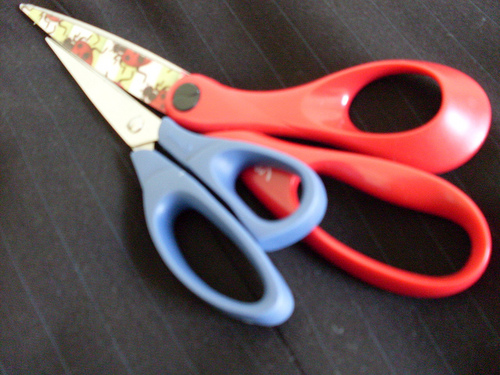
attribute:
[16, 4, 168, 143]
blades — stainless steel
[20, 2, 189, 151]
blades — sharp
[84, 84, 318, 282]
scissors — blue, small, color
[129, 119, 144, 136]
screw — silver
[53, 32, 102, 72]
bug — color, black, red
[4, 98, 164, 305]
table — brown 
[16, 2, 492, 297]
scissors — red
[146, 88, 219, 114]
screw — metal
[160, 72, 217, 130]
screw — black 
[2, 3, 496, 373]
cloth — black, white, striped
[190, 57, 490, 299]
handle — red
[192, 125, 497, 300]
scissor handle — blue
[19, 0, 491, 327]
scissors — patterned, sharp, metal, blue, red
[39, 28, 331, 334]
scissors — silver, blue, large